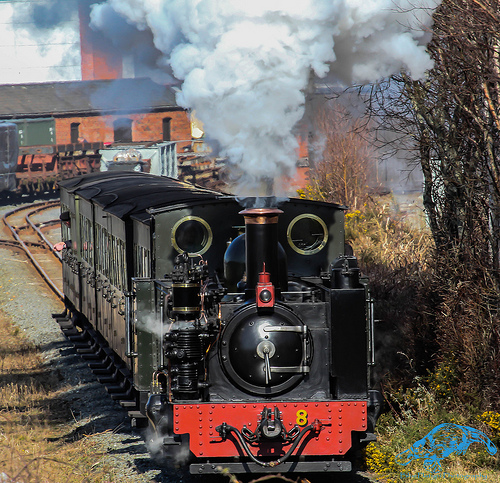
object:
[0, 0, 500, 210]
cloud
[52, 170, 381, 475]
locomotive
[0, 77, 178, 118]
roof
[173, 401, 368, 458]
red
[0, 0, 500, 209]
smoke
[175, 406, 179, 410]
bolts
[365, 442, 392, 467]
leaves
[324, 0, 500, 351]
tree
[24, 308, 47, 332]
ground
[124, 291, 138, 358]
handle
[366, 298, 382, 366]
handle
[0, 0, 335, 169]
cloud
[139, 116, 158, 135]
wall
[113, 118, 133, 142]
door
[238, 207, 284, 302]
pipe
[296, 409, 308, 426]
number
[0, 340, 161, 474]
shadow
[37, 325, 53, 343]
gravel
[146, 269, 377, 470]
front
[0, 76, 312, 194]
building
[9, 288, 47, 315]
gravel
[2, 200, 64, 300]
tracks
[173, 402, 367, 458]
bumper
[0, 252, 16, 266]
ground